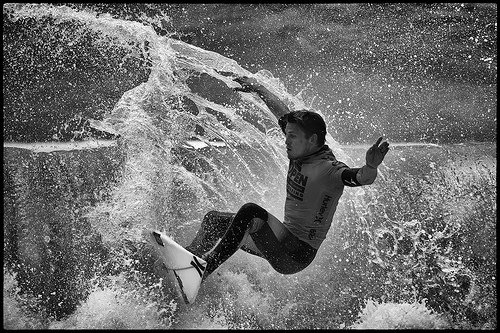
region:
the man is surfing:
[129, 64, 419, 313]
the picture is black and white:
[12, 13, 489, 325]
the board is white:
[134, 208, 226, 314]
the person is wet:
[160, 42, 396, 313]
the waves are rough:
[36, 36, 203, 243]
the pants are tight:
[171, 165, 337, 325]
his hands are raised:
[225, 45, 407, 214]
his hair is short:
[265, 99, 335, 192]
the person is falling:
[135, 66, 393, 317]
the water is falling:
[20, 11, 176, 291]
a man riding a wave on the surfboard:
[131, 59, 391, 300]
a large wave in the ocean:
[3, 140, 498, 324]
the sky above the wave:
[2, 0, 498, 140]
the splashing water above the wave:
[18, 2, 263, 137]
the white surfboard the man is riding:
[134, 224, 208, 305]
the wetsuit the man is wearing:
[193, 150, 368, 296]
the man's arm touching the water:
[232, 73, 285, 115]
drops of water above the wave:
[318, 9, 486, 144]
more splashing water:
[360, 231, 476, 331]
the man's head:
[283, 108, 323, 163]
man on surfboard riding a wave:
[139, 75, 398, 317]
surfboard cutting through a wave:
[145, 204, 217, 306]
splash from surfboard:
[95, 20, 199, 265]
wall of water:
[403, 137, 498, 219]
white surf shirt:
[270, 146, 360, 274]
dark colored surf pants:
[199, 205, 327, 295]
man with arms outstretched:
[231, 65, 392, 195]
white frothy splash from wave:
[341, 287, 453, 327]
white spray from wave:
[305, 13, 425, 83]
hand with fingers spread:
[364, 138, 398, 172]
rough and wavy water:
[0, 1, 498, 331]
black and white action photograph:
[1, 1, 496, 331]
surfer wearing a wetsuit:
[183, 73, 390, 283]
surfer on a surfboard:
[148, 75, 390, 310]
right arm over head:
[231, 74, 328, 160]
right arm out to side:
[285, 136, 390, 187]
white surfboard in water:
[148, 227, 208, 305]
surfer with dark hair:
[182, 75, 391, 280]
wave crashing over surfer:
[12, 2, 354, 273]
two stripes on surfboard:
[189, 253, 207, 279]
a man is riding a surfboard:
[104, 63, 372, 297]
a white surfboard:
[140, 219, 219, 320]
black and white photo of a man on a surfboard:
[26, 25, 493, 311]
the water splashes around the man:
[73, 12, 229, 214]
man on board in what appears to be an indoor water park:
[16, 11, 474, 313]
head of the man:
[281, 112, 332, 154]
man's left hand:
[365, 134, 392, 171]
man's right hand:
[231, 69, 266, 99]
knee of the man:
[234, 197, 263, 228]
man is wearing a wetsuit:
[196, 150, 358, 285]